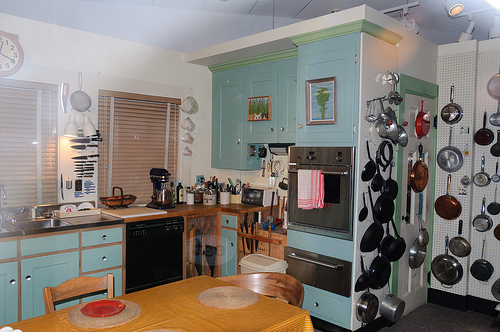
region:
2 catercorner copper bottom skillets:
[401, 136, 463, 231]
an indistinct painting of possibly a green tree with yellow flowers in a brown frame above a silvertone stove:
[302, 73, 339, 128]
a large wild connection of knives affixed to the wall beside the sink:
[66, 121, 103, 199]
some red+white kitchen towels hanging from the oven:
[293, 165, 328, 214]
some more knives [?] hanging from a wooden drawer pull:
[232, 212, 279, 262]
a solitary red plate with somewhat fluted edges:
[78, 293, 126, 320]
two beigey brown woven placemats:
[63, 281, 262, 329]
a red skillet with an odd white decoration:
[408, 96, 435, 141]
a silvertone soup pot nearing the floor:
[377, 269, 407, 329]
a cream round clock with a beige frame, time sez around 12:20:
[0, 28, 28, 78]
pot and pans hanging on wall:
[362, 57, 499, 322]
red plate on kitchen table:
[70, 287, 142, 324]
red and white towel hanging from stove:
[294, 163, 334, 215]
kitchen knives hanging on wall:
[67, 124, 104, 181]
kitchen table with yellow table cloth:
[163, 254, 290, 324]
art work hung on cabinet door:
[301, 67, 341, 129]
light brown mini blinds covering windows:
[101, 90, 183, 190]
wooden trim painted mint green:
[281, 17, 400, 59]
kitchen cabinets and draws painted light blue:
[23, 224, 125, 284]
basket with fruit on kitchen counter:
[100, 181, 147, 212]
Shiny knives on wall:
[70, 113, 109, 186]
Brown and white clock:
[2, 23, 30, 95]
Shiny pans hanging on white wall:
[436, 53, 496, 305]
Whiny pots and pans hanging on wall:
[349, 70, 442, 330]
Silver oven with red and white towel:
[286, 141, 358, 245]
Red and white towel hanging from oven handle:
[299, 165, 326, 218]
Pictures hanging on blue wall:
[231, 76, 349, 136]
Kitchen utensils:
[170, 80, 208, 170]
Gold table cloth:
[61, 275, 339, 330]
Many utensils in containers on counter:
[176, 170, 277, 220]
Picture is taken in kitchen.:
[30, 45, 480, 300]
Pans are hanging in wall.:
[382, 65, 477, 326]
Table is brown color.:
[147, 298, 242, 328]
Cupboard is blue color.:
[7, 250, 69, 276]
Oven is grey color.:
[295, 146, 346, 232]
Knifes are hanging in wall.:
[65, 120, 96, 195]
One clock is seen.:
[0, 28, 36, 84]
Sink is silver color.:
[0, 172, 62, 240]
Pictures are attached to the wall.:
[232, 77, 350, 125]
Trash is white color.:
[238, 247, 295, 282]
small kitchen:
[12, 66, 384, 321]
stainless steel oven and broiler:
[290, 146, 347, 294]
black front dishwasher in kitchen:
[102, 204, 197, 277]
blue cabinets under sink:
[0, 236, 121, 288]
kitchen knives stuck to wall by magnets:
[56, 116, 105, 206]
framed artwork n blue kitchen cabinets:
[233, 69, 339, 136]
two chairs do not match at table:
[37, 244, 305, 324]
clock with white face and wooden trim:
[5, 15, 32, 100]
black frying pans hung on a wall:
[356, 129, 418, 299]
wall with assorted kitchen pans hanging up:
[362, 56, 495, 313]